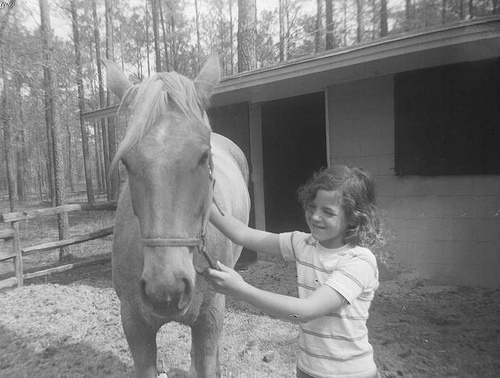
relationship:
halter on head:
[142, 235, 214, 275] [93, 43, 225, 318]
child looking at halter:
[210, 161, 393, 376] [135, 234, 216, 267]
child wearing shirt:
[210, 161, 393, 376] [284, 241, 372, 373]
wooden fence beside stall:
[5, 206, 110, 267] [234, 67, 367, 165]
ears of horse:
[94, 47, 225, 103] [99, 46, 251, 376]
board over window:
[387, 59, 499, 187] [378, 60, 499, 182]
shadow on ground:
[6, 336, 108, 373] [39, 202, 478, 361]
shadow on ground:
[39, 244, 118, 289] [39, 202, 478, 361]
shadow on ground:
[384, 295, 496, 376] [39, 202, 478, 361]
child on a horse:
[210, 161, 393, 377] [99, 46, 251, 376]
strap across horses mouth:
[140, 235, 201, 247] [139, 226, 193, 314]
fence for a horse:
[2, 197, 120, 287] [99, 46, 251, 376]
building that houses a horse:
[215, 15, 498, 293] [99, 46, 251, 376]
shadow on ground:
[1, 320, 133, 376] [1, 206, 203, 373]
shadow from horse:
[1, 320, 133, 376] [85, 46, 266, 373]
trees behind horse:
[38, 3, 80, 258] [100, 49, 236, 376]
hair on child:
[296, 161, 391, 270] [210, 161, 393, 377]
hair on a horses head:
[100, 66, 205, 158] [93, 43, 225, 318]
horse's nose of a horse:
[136, 273, 199, 321] [99, 46, 251, 376]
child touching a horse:
[210, 161, 393, 377] [99, 46, 251, 376]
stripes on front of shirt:
[286, 231, 379, 375] [277, 230, 379, 377]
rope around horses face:
[133, 232, 201, 250] [119, 68, 216, 317]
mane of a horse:
[104, 68, 206, 179] [99, 46, 251, 376]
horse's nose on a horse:
[136, 273, 199, 321] [85, 46, 266, 373]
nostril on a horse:
[169, 264, 197, 305] [99, 46, 251, 376]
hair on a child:
[296, 161, 391, 270] [210, 161, 393, 377]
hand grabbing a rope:
[204, 260, 244, 297] [198, 212, 240, 303]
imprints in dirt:
[7, 314, 116, 375] [401, 299, 487, 376]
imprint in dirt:
[253, 337, 276, 352] [62, 249, 499, 376]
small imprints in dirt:
[397, 288, 478, 354] [1, 194, 496, 375]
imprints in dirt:
[86, 286, 121, 339] [387, 291, 490, 372]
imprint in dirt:
[82, 325, 98, 338] [419, 325, 483, 370]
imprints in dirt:
[431, 294, 488, 357] [401, 287, 485, 369]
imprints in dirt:
[243, 324, 268, 360] [1, 194, 496, 375]